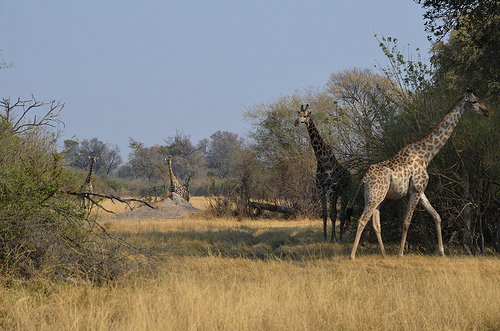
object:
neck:
[424, 102, 468, 161]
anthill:
[99, 191, 194, 222]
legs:
[351, 193, 384, 255]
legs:
[372, 204, 385, 254]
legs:
[400, 191, 421, 252]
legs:
[420, 193, 445, 252]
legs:
[317, 187, 328, 236]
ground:
[0, 194, 496, 326]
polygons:
[375, 162, 427, 188]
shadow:
[248, 231, 302, 252]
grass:
[0, 195, 499, 330]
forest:
[1, 0, 498, 327]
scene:
[16, 21, 496, 308]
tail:
[343, 181, 363, 223]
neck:
[306, 123, 341, 167]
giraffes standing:
[341, 88, 489, 261]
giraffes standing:
[293, 104, 356, 243]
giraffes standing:
[76, 156, 97, 214]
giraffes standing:
[166, 155, 189, 203]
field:
[1, 190, 496, 326]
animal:
[347, 88, 489, 261]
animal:
[293, 103, 355, 243]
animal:
[166, 153, 188, 200]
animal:
[78, 156, 96, 214]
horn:
[305, 104, 309, 110]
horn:
[300, 105, 304, 111]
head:
[294, 104, 309, 127]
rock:
[108, 190, 198, 220]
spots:
[388, 158, 413, 177]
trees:
[56, 129, 253, 187]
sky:
[0, 1, 472, 138]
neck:
[168, 163, 178, 183]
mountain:
[418, 0, 495, 249]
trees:
[0, 95, 64, 274]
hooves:
[439, 251, 445, 258]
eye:
[472, 101, 477, 104]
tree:
[235, 170, 298, 220]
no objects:
[285, 253, 365, 312]